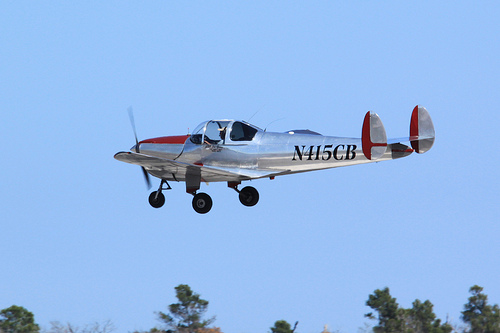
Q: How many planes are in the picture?
A: One plane.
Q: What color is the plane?
A: Silver and red.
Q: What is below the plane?
A: The trees.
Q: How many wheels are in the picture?
A: Three wheels.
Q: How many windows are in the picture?
A: Three windows.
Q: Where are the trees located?
A: Under the plane.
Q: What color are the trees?
A: Green.